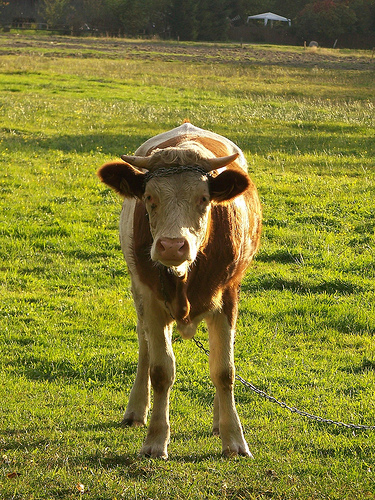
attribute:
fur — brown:
[105, 168, 127, 187]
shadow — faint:
[10, 345, 138, 387]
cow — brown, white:
[92, 118, 268, 460]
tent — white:
[245, 8, 296, 28]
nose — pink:
[155, 232, 189, 261]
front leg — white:
[137, 292, 176, 459]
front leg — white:
[209, 282, 253, 455]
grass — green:
[1, 32, 363, 496]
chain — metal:
[193, 336, 363, 432]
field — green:
[1, 32, 363, 496]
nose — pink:
[156, 237, 186, 261]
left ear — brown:
[210, 169, 252, 203]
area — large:
[2, 31, 363, 497]